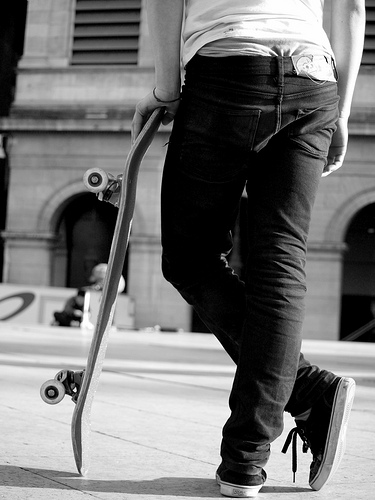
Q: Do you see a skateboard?
A: Yes, there is a skateboard.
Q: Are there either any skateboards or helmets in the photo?
A: Yes, there is a skateboard.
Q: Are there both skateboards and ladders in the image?
A: No, there is a skateboard but no ladders.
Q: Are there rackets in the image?
A: No, there are no rackets.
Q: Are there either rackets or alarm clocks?
A: No, there are no rackets or alarm clocks.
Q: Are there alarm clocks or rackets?
A: No, there are no rackets or alarm clocks.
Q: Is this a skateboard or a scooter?
A: This is a skateboard.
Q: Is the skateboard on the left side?
A: Yes, the skateboard is on the left of the image.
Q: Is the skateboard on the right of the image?
A: No, the skateboard is on the left of the image.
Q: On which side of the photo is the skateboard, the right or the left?
A: The skateboard is on the left of the image.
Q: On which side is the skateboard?
A: The skateboard is on the left of the image.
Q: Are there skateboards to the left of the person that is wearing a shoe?
A: Yes, there is a skateboard to the left of the person.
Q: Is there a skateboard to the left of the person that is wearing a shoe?
A: Yes, there is a skateboard to the left of the person.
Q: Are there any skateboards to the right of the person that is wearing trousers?
A: No, the skateboard is to the left of the person.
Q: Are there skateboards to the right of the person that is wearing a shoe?
A: No, the skateboard is to the left of the person.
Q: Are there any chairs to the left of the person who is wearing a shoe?
A: No, there is a skateboard to the left of the person.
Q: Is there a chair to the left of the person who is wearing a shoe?
A: No, there is a skateboard to the left of the person.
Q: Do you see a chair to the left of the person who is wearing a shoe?
A: No, there is a skateboard to the left of the person.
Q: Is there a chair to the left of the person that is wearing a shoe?
A: No, there is a skateboard to the left of the person.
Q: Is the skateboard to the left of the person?
A: Yes, the skateboard is to the left of the person.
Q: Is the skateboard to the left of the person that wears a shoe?
A: Yes, the skateboard is to the left of the person.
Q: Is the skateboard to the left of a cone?
A: No, the skateboard is to the left of the person.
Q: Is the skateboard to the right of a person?
A: No, the skateboard is to the left of a person.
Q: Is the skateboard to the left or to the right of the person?
A: The skateboard is to the left of the person.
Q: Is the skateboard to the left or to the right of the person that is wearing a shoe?
A: The skateboard is to the left of the person.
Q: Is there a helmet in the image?
A: No, there are no helmets.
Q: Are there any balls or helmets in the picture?
A: No, there are no helmets or balls.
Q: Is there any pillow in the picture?
A: No, there are no pillows.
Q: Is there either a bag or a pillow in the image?
A: No, there are no pillows or bags.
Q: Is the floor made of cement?
A: Yes, the floor is made of cement.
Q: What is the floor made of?
A: The floor is made of concrete.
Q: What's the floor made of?
A: The floor is made of concrete.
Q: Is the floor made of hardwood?
A: No, the floor is made of cement.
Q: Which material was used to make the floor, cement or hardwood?
A: The floor is made of cement.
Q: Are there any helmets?
A: No, there are no helmets.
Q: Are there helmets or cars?
A: No, there are no helmets or cars.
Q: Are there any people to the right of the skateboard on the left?
A: Yes, there is a person to the right of the skateboard.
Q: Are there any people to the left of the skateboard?
A: No, the person is to the right of the skateboard.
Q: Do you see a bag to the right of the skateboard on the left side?
A: No, there is a person to the right of the skateboard.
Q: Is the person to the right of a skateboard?
A: Yes, the person is to the right of a skateboard.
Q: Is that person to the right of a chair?
A: No, the person is to the right of a skateboard.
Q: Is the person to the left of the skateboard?
A: No, the person is to the right of the skateboard.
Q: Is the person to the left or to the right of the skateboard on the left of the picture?
A: The person is to the right of the skateboard.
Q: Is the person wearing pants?
A: Yes, the person is wearing pants.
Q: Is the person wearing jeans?
A: No, the person is wearing pants.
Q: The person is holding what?
A: The person is holding the skateboard.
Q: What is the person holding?
A: The person is holding the skateboard.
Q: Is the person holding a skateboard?
A: Yes, the person is holding a skateboard.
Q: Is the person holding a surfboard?
A: No, the person is holding a skateboard.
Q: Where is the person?
A: The person is at the skateboard.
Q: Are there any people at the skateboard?
A: Yes, there is a person at the skateboard.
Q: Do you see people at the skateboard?
A: Yes, there is a person at the skateboard.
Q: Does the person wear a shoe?
A: Yes, the person wears a shoe.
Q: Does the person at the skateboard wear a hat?
A: No, the person wears a shoe.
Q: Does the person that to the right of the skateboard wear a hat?
A: No, the person wears a shoe.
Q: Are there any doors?
A: Yes, there is a door.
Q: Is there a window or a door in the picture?
A: Yes, there is a door.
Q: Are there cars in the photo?
A: No, there are no cars.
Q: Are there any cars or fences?
A: No, there are no cars or fences.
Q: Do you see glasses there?
A: No, there are no glasses.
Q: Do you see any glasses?
A: No, there are no glasses.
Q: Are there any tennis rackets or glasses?
A: No, there are no glasses or tennis rackets.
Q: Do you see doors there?
A: Yes, there is a door.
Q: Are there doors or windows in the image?
A: Yes, there is a door.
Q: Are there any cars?
A: No, there are no cars.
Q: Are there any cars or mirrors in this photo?
A: No, there are no cars or mirrors.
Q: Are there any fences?
A: No, there are no fences.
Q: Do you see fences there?
A: No, there are no fences.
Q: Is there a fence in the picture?
A: No, there are no fences.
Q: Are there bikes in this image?
A: No, there are no bikes.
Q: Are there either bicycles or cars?
A: No, there are no bicycles or cars.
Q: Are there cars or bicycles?
A: No, there are no bicycles or cars.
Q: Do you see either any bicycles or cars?
A: No, there are no bicycles or cars.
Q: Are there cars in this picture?
A: No, there are no cars.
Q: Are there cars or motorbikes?
A: No, there are no cars or motorbikes.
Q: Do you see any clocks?
A: No, there are no clocks.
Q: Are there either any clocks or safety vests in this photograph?
A: No, there are no clocks or safety vests.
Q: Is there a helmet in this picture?
A: No, there are no helmets.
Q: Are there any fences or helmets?
A: No, there are no helmets or fences.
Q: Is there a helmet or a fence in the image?
A: No, there are no helmets or fences.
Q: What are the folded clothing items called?
A: The clothing items are pants.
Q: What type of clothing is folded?
A: The clothing is pants.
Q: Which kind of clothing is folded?
A: The clothing is pants.